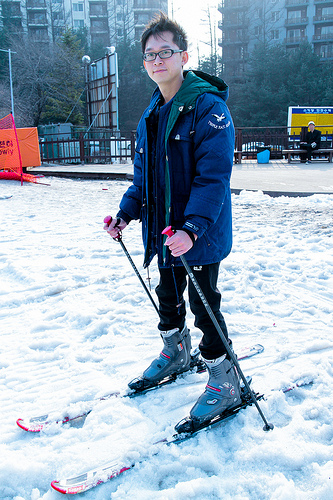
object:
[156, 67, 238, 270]
part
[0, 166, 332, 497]
snow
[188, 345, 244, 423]
boot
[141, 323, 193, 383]
boot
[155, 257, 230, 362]
trouser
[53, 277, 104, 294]
lines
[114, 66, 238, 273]
jacket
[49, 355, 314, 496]
skis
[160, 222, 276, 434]
stick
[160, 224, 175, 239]
handle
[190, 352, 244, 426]
shoe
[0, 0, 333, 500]
place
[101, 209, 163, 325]
ski pole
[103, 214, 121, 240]
handle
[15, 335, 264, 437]
ski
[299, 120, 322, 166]
man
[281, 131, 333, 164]
bench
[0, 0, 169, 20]
floor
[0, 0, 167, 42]
floor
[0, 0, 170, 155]
building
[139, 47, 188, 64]
eyeglasses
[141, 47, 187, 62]
frame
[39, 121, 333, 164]
fence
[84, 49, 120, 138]
sign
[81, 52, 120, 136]
back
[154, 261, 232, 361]
pants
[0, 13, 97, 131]
group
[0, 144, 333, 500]
ground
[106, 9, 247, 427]
boy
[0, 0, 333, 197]
city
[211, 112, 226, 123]
bird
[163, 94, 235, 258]
arm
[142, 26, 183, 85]
face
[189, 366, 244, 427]
feet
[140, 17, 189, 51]
hair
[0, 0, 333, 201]
background